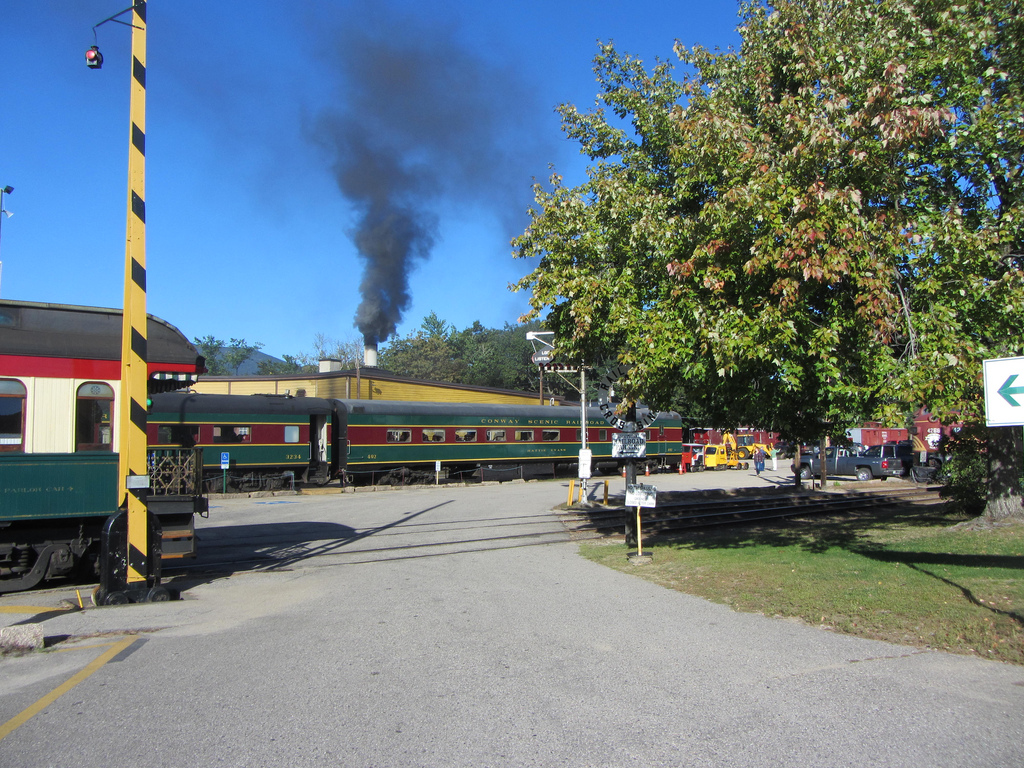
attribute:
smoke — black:
[284, 48, 492, 347]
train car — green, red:
[331, 383, 697, 487]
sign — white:
[984, 395, 991, 424]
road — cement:
[15, 447, 1016, 763]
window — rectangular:
[195, 417, 250, 454]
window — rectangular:
[385, 421, 433, 469]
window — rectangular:
[426, 421, 481, 461]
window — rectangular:
[449, 410, 489, 450]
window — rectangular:
[475, 417, 534, 472]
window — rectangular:
[508, 421, 537, 454]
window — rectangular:
[534, 414, 571, 451]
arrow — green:
[985, 365, 1022, 402]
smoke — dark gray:
[128, 26, 578, 353]